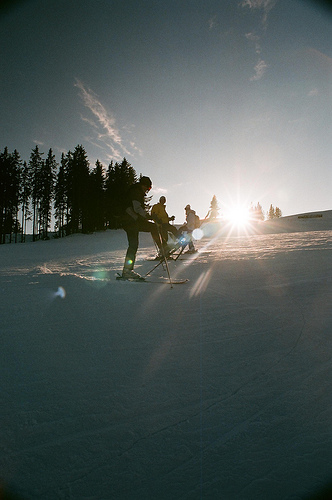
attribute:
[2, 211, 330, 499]
snow — white, powdery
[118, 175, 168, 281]
person — standing on one foot, skiing, skier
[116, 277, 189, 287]
skis — snow skis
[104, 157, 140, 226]
tree — large, evergreen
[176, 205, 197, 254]
person — skiing, skier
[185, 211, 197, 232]
jacket — white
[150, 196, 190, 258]
person — skiing, skier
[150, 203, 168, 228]
jacket — yellow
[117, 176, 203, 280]
people — skiing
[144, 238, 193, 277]
ski — long, wooden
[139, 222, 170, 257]
leg — raised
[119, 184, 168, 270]
outfit — dark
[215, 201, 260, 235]
sun — on the horizon, going down, emitting rays, white, bright, setting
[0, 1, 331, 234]
sky — dark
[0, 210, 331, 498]
hill — snowy